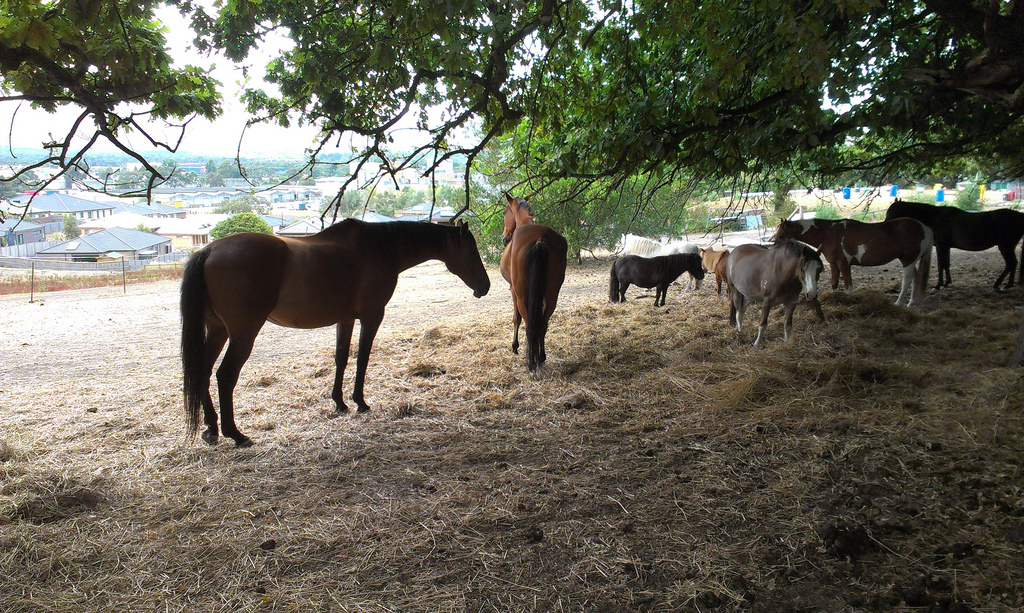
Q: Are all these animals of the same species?
A: Yes, all the animals are horses.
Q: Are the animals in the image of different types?
A: No, all the animals are horses.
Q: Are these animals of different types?
A: No, all the animals are horses.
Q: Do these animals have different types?
A: No, all the animals are horses.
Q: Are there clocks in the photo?
A: No, there are no clocks.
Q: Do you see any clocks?
A: No, there are no clocks.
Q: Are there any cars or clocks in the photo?
A: No, there are no clocks or cars.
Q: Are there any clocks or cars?
A: No, there are no clocks or cars.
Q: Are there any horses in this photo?
A: Yes, there are horses.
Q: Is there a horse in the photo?
A: Yes, there are horses.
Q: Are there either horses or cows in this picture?
A: Yes, there are horses.